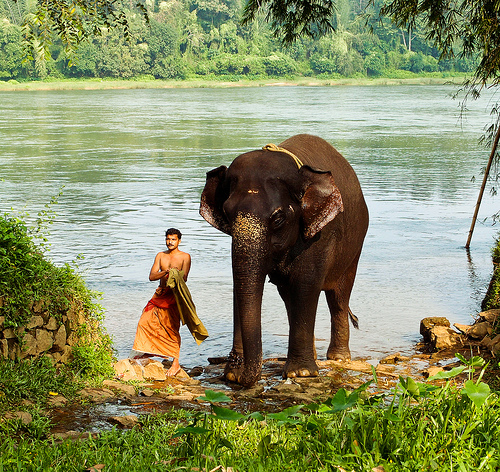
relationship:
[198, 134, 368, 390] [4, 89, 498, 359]
elephant leaving water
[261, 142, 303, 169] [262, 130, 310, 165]
rope around a neck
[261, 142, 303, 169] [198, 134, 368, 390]
rope around an elephant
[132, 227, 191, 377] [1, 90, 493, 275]
man coming out of water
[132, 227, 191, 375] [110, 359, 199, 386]
man on rocks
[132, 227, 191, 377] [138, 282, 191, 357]
man wearing cloth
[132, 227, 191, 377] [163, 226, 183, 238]
man has hair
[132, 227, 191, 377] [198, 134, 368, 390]
man standing next to elephant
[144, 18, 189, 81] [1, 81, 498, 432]
bushes by water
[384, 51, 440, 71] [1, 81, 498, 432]
bushes by water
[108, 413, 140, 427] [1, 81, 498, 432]
rocks next to water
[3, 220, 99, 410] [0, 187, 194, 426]
plants growing on rock wall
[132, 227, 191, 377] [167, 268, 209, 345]
man holding cloth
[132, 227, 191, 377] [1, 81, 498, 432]
man on water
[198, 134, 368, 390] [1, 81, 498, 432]
elephant on water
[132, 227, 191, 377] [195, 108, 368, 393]
man and h elephant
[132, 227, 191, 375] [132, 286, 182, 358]
man wearing a cloth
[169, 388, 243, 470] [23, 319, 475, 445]
grass by water's edge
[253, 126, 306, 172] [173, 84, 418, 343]
rope around neck of elephant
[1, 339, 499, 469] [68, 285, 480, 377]
grass at water's edge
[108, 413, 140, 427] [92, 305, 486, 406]
rocks at water's edge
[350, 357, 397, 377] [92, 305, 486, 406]
rocks at water's edge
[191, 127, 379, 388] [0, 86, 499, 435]
elephant standing near river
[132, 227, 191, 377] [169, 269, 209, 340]
man holding cloth